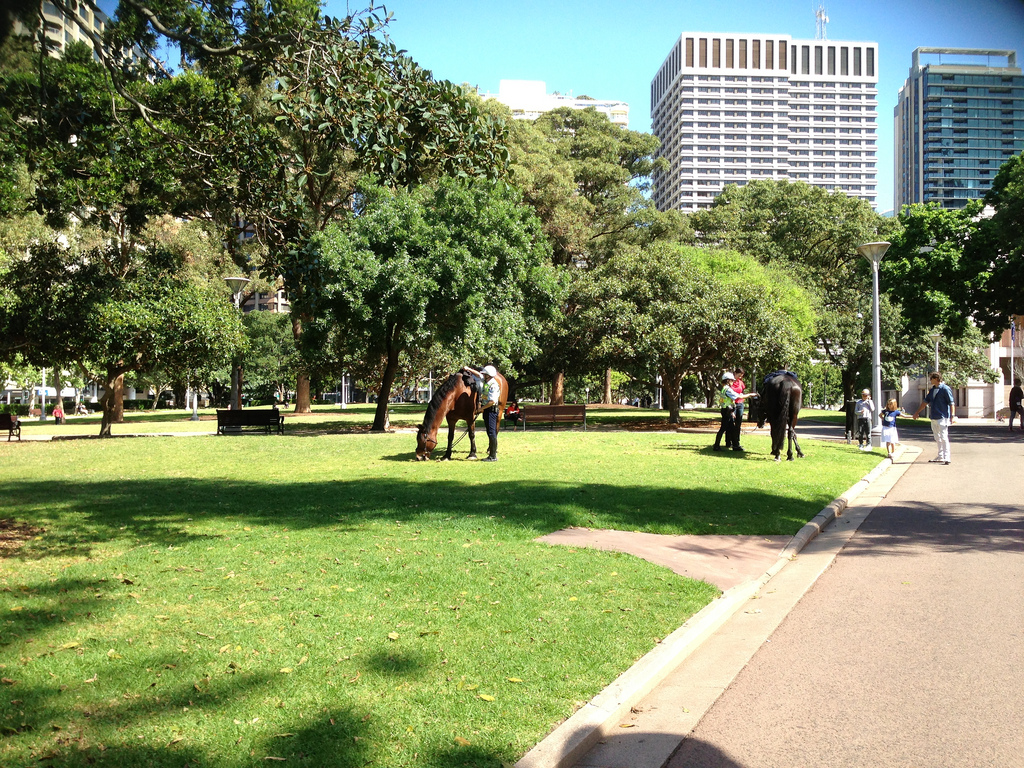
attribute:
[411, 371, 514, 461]
horse — brown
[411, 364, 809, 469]
horses — background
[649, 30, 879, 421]
building — large, tall, white, windowed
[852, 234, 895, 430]
lightpost — tall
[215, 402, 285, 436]
bench — wooden, distant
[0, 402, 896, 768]
grass — shady, green, greeny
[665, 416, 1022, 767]
walkway — asphalt, gray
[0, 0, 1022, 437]
trees — green, background, bushy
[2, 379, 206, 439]
people — background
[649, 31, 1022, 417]
buildings — modern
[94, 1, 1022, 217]
sky — blue